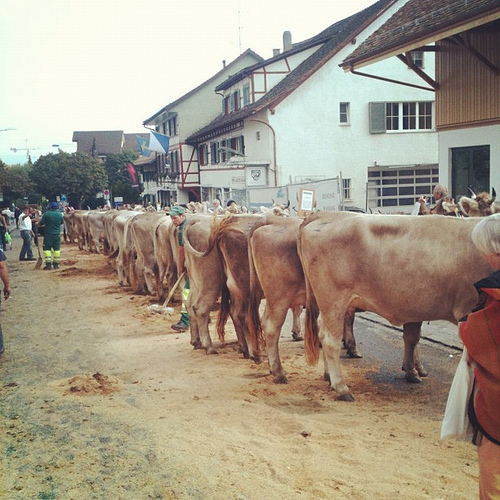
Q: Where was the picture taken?
A: On a street.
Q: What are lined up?
A: Cows.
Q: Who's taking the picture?
A: A photographer.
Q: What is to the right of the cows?
A: Houses.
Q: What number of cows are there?
A: Over 10.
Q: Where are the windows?
A: On the white house.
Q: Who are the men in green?
A: They are taking care of the cows.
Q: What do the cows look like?
A: The cows are light brown.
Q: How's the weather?
A: Cool and cloudy.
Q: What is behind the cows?
A: Pile of dirt.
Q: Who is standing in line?
A: The cows.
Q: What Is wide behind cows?
A: The buildings.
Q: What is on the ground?
A: The dirt.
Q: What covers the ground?
A: Sawdust and cow manure.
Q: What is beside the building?
A: Chain link fence.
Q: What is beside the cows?
A: Two large white buildings.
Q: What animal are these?
A: Cows.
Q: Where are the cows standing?
A: In front of the building.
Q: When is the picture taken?
A: Daytime.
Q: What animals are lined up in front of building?
A: Cows.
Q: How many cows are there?
A: Twelve.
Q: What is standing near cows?
A: People.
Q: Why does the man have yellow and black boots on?
A: For walking in mud.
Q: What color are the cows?
A: Brown.